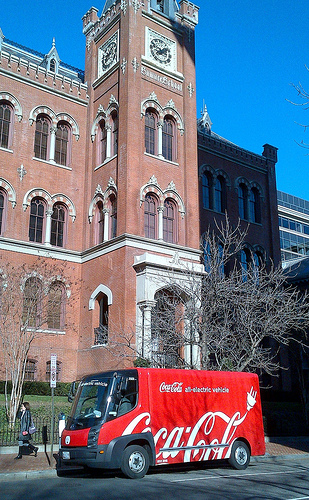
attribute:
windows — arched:
[139, 184, 195, 241]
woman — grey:
[14, 401, 39, 458]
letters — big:
[121, 410, 247, 466]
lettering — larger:
[130, 406, 237, 459]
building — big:
[0, 0, 283, 384]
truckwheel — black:
[231, 441, 250, 467]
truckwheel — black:
[124, 445, 149, 476]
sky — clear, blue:
[195, 1, 306, 199]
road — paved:
[0, 453, 307, 498]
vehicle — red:
[52, 361, 268, 484]